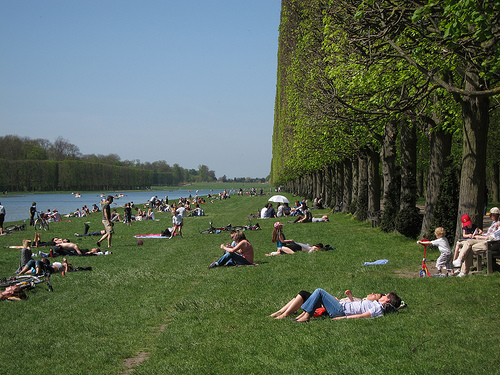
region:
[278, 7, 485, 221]
Row of tall green trees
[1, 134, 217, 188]
Row of green trees in the distance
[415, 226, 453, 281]
Child riding a red scooter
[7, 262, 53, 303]
Bicycle laying in the green grass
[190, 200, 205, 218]
Person wearing light blue shirt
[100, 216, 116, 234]
Person wearing khaki shorts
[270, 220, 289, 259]
Girl kneeling in grass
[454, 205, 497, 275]
Person sitting on wood bench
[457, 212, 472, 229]
Child wearing red cap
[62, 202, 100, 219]
Group of people sitting in the grass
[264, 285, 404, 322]
two women laying in the grass side by side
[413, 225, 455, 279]
a boy on a red scooter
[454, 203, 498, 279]
a woman sitting on a chair with a child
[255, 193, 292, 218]
a small group of people sitting under a white umbrella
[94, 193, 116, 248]
a man with tan shorts walking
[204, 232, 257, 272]
a man and woman seated together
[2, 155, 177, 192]
a line of trees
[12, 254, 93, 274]
a woman lying on her back with knees upraised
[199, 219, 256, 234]
a bicycle lying on its side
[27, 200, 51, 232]
a person holding the handlebars of a bicycle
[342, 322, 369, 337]
part of a grass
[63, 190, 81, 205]
part of a river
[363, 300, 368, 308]
part of a shirt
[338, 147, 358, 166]
edge of a tree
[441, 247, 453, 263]
back of a boy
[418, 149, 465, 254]
tip of a stem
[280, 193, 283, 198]
part of an umbrella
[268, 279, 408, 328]
people laying on grass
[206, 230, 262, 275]
people laying on grass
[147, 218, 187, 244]
people laying on grass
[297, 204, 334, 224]
people laying on grass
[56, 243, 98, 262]
people laying on grass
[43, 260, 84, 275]
people laying on grass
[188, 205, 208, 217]
people laying on grass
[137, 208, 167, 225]
people laying on grass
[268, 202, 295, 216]
people laying on grass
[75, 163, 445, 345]
people at the park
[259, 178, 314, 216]
the umbrella is white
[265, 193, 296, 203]
the umbrella is white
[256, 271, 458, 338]
the couples are lying down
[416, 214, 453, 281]
a kid riding a scooter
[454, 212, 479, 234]
the cap is red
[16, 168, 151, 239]
people beside the river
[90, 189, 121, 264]
the man is walking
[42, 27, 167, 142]
the sky is clear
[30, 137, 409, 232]
the trees are lined up